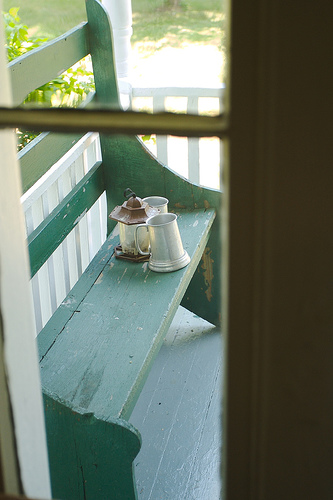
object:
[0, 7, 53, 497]
drape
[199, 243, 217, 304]
peeling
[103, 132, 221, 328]
leg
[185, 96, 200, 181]
rail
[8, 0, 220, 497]
wood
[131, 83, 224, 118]
railiing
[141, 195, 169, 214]
mug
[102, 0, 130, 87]
post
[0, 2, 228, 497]
porch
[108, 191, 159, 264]
feeder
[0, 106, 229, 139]
window trim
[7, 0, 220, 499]
bench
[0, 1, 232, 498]
window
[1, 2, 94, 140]
bushes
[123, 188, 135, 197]
hook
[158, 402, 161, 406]
speck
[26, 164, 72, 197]
bannister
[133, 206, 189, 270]
cup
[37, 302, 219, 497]
deck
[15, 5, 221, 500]
wooden bench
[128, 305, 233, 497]
deck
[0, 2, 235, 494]
panel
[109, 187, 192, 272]
objects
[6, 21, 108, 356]
back